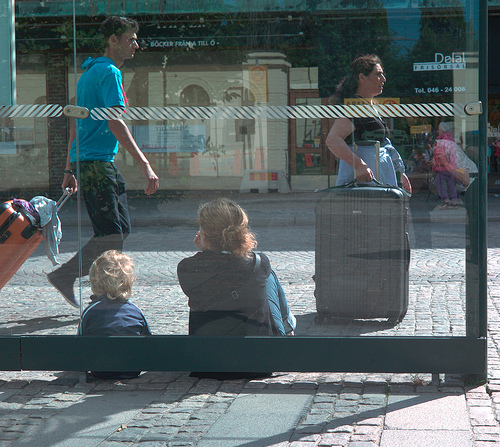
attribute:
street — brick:
[324, 391, 375, 415]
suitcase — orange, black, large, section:
[305, 183, 412, 318]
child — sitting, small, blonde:
[71, 242, 146, 371]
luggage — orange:
[1, 222, 33, 268]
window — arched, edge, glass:
[356, 23, 405, 49]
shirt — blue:
[79, 81, 102, 103]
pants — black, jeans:
[82, 183, 128, 241]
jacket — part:
[242, 262, 272, 295]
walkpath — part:
[263, 211, 290, 228]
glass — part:
[314, 3, 372, 31]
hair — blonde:
[194, 205, 231, 229]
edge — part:
[459, 393, 485, 408]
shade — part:
[186, 4, 224, 32]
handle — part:
[48, 194, 70, 211]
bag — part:
[435, 141, 475, 173]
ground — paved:
[267, 247, 300, 273]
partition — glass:
[221, 5, 270, 41]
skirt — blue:
[360, 154, 391, 180]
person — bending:
[420, 141, 431, 194]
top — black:
[359, 120, 375, 133]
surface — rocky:
[138, 208, 180, 228]